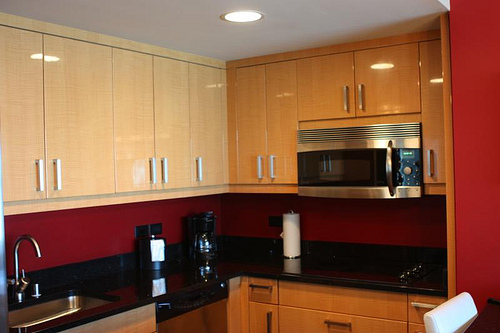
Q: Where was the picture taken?
A: In the kitchen.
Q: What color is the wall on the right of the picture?
A: Red.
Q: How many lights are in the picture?
A: One.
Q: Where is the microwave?
A: Over the range.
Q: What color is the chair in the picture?
A: White.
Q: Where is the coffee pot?
A: On the countertop.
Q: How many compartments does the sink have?
A: One.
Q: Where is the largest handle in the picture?
A: On the microwave.